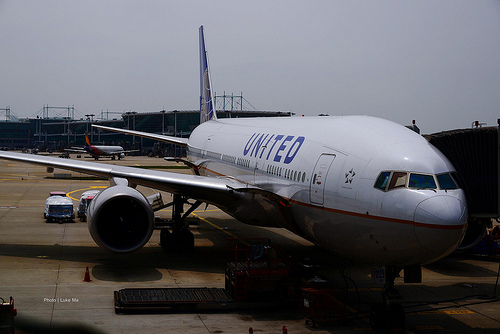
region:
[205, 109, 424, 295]
the plane is white in color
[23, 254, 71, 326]
the floor is brown in color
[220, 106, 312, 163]
the words are written on white part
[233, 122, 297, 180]
the words are written in blue color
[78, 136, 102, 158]
the plane tail is blue and red in color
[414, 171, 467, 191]
the plane windows are blue in color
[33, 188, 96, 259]
the car is light blue in color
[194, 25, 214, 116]
the plane tail is blue in color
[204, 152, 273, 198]
the plane windows are colorles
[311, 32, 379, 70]
the sky is dull blue in color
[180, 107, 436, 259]
A white united plan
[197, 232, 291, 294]
A red offloading truck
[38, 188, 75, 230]
A white truck at the airport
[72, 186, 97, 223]
A white truck at the airport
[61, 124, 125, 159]
A white and orange plane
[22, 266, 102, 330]
A cemented airport floor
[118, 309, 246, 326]
A cemented airport floor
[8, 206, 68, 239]
A cemented airport floor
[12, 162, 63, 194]
A cemented airport floor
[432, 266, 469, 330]
A cemented airport floor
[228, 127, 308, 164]
the blue lettering on the plane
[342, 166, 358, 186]
the arrows on the planes front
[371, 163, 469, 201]
the windshield on the airplane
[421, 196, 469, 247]
the nose of the plane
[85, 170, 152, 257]
the turbine engine on the wing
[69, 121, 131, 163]
the plane driving on the runway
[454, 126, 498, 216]
the tunnel going into the plane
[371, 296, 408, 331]
the front wheels of the plane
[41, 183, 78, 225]
the cart with a trailer of stuff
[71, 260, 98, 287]
the orange cone under the plane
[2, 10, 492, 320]
A beautiful scene of an airport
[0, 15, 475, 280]
A flight belonging to the united air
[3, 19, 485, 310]
A tall tail position of an aircraft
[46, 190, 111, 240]
Vehicles are parked near the aircraft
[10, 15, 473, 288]
Beautiful cockpit of an aircraft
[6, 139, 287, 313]
Turbine engine of an aircraft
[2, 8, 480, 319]
Wheels of an aircraft near the engine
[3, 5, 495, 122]
Sky is extremely cloudy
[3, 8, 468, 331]
A big building is behind the aircraft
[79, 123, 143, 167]
An aircraft with different colors on its nose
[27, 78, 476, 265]
a large white plane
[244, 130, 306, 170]
writing on the plane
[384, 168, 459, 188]
windows in the front of the plane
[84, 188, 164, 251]
the propeller of the plane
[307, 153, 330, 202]
the door of the plane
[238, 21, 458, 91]
the clear sky behind the plane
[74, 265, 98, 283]
a cone beside the plane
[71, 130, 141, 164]
an airplane in the background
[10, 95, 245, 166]
a building behind the plane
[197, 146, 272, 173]
windows of the plane